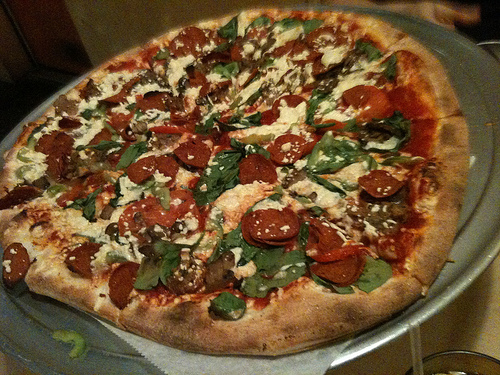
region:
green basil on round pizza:
[5, 2, 465, 361]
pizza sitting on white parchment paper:
[0, 0, 499, 373]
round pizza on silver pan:
[5, 5, 498, 371]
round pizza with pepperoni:
[4, 0, 497, 362]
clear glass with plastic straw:
[401, 318, 498, 367]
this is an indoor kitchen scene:
[5, 0, 498, 368]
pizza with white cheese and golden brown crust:
[0, 4, 497, 361]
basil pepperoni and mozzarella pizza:
[6, 0, 472, 363]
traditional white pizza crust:
[3, 6, 474, 361]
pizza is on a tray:
[3, 4, 498, 374]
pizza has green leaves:
[208, 218, 318, 298]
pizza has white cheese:
[22, 14, 414, 292]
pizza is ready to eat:
[6, 7, 474, 354]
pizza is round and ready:
[2, 9, 469, 356]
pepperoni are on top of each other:
[239, 205, 302, 250]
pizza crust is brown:
[2, 202, 459, 356]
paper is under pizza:
[68, 304, 354, 374]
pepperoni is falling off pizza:
[0, 243, 31, 285]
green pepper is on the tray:
[52, 324, 84, 360]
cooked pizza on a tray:
[8, 8, 460, 328]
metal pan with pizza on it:
[2, 5, 497, 368]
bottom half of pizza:
[9, 118, 461, 355]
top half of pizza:
[26, 4, 477, 131]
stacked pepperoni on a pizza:
[242, 204, 301, 255]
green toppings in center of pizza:
[197, 145, 240, 198]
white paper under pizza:
[85, 317, 360, 373]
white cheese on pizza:
[238, 96, 317, 136]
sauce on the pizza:
[389, 78, 434, 158]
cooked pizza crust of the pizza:
[153, 278, 423, 350]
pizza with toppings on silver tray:
[7, 6, 483, 358]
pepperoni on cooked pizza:
[239, 207, 366, 288]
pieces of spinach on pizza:
[244, 251, 294, 293]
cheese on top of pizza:
[214, 184, 259, 219]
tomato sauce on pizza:
[406, 107, 437, 151]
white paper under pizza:
[171, 340, 360, 374]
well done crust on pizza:
[160, 297, 346, 342]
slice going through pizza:
[344, 205, 438, 302]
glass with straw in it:
[388, 319, 498, 373]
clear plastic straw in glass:
[392, 308, 434, 373]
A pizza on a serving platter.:
[5, 5, 483, 366]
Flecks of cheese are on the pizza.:
[25, 16, 455, 321]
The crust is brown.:
[175, 300, 407, 345]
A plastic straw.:
[391, 315, 432, 370]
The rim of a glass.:
[395, 337, 497, 369]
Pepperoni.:
[235, 195, 295, 242]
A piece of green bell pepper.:
[45, 315, 95, 360]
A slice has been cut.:
[205, 110, 490, 270]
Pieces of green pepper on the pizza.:
[10, 125, 100, 210]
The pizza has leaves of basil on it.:
[60, 15, 431, 305]